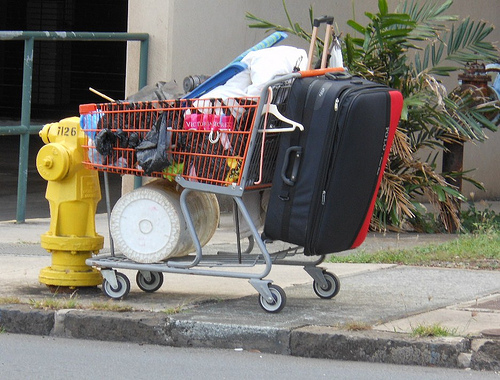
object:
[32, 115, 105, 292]
fire hydrant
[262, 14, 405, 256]
suitcase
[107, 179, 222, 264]
bucket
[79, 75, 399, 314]
buggy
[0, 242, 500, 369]
sidewalk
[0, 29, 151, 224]
railings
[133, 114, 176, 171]
plastic